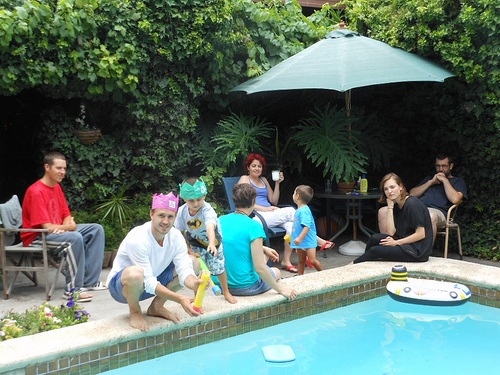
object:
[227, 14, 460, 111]
umbrella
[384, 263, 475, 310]
floaty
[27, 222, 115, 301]
pants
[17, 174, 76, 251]
shirt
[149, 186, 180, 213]
crown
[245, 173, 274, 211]
tank top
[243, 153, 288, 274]
woman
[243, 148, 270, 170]
red hair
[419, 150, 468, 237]
man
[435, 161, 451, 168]
glasses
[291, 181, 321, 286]
toddler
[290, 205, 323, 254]
shirt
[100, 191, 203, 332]
man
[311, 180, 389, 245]
table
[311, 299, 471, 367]
water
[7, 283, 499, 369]
swimming pool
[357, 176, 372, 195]
cup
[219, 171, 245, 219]
patio chair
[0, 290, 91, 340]
garden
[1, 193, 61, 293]
chair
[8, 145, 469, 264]
people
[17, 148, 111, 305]
man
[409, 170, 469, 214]
black shirt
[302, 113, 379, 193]
plant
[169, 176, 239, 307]
boy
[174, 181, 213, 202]
crown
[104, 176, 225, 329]
two people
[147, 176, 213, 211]
crowns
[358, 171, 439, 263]
person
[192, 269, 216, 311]
toy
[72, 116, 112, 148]
basket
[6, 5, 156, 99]
tree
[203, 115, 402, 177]
palms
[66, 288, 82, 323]
flowers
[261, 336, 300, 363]
board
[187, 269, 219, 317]
squirt guns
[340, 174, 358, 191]
pot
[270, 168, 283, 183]
mug